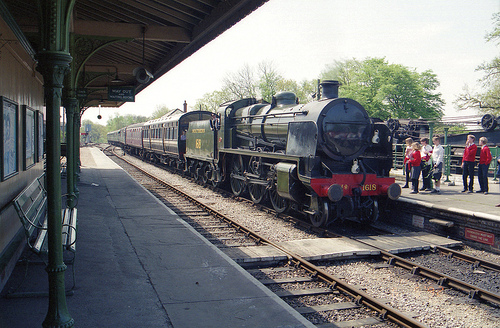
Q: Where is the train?
A: A station.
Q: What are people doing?
A: Waiting to board.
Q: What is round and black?
A: The engine.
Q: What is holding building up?
A: Green columns.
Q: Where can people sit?
A: On bench.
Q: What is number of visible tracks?
A: Two.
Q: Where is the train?
A: At a station.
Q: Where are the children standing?
A: On the train platform.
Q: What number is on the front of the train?
A: 1618.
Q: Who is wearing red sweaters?
A: Children on the platform.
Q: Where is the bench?
A: Next to the depot.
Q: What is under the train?
A: Railroad tracks.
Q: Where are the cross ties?
A: Under the rails.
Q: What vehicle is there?
A: Train.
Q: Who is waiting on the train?
A: Passengers.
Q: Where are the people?
A: Outside train.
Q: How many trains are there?
A: One.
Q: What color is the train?
A: Black.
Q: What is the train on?
A: Tracks.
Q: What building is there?
A: Train station.